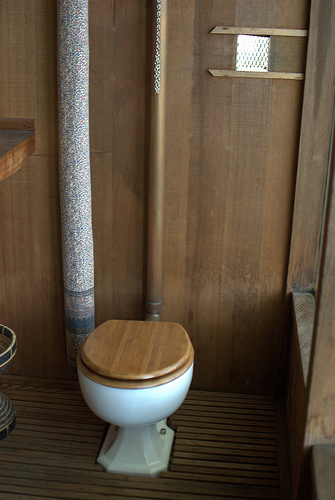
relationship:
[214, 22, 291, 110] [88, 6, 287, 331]
mirror attached wall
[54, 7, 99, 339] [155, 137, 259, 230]
pipe for tiolet attached wall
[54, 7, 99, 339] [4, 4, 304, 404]
pipe for tiolet attached to wall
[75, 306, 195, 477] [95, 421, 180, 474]
one toilet with porcelain base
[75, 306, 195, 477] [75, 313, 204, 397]
one toilet with toilet seat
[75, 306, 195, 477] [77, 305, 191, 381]
one toilet with toilet seat top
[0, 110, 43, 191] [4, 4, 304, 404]
wooden shelf attached to wall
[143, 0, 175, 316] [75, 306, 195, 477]
this is a pipe for one toilet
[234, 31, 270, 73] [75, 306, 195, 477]
small glass window above one toilet